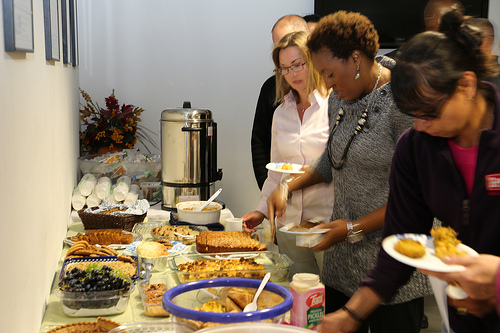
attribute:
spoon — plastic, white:
[241, 266, 274, 317]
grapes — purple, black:
[59, 262, 129, 309]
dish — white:
[173, 197, 224, 227]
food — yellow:
[181, 202, 217, 212]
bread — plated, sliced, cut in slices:
[69, 227, 135, 246]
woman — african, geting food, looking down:
[269, 8, 438, 329]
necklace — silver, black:
[322, 61, 382, 172]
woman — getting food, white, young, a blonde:
[240, 31, 352, 281]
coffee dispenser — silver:
[157, 99, 225, 211]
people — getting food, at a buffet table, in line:
[242, 1, 500, 332]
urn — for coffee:
[156, 99, 228, 213]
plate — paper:
[278, 212, 335, 238]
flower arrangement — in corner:
[76, 80, 161, 155]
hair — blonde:
[271, 29, 329, 103]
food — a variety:
[46, 188, 321, 332]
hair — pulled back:
[386, 5, 489, 122]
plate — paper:
[264, 155, 310, 178]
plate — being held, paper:
[379, 226, 481, 276]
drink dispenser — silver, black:
[157, 99, 225, 211]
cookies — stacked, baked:
[63, 237, 123, 258]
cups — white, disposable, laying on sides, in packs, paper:
[70, 171, 143, 212]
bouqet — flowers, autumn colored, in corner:
[72, 83, 160, 160]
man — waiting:
[248, 13, 313, 191]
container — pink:
[287, 268, 325, 332]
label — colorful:
[305, 289, 328, 329]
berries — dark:
[60, 264, 126, 296]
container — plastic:
[160, 276, 296, 331]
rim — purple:
[162, 276, 295, 324]